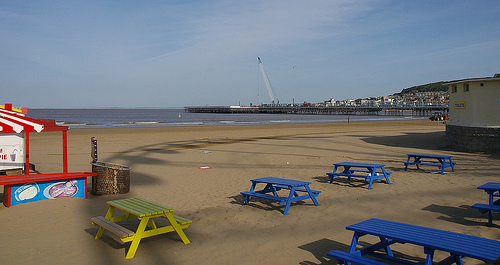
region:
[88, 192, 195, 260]
Yellow picnic table and benches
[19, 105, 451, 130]
The water appears calm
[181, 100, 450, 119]
The pier is long above the water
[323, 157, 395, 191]
Blue picnic table and benches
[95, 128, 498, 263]
Shadows on the sand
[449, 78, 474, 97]
Two windows side by side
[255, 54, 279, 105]
White smoke behind a small jet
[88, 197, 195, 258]
yellow picnic bench at beach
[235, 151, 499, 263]
blue picnic benches on beach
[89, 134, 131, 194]
large rock trash bin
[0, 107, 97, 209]
red wooden food stand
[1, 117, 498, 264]
golden sand on beach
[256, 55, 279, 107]
man is flying water rockets on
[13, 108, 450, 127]
water is dark blue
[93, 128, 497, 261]
shadow cast on sand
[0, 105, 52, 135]
red and white awning on food stand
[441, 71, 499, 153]
creme and brick building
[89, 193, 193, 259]
Yellow picnic bench on the sand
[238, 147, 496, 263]
Blue picnic benches on the sand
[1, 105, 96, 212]
Empty food stand on the beach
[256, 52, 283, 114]
Crane in the distance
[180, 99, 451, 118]
Pier jetting out into the water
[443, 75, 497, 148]
Building at the beach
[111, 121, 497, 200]
Shadows in the sand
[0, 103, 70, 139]
Red and white awning on food structure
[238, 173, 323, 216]
Blue picnic bench on the sand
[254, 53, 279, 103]
crane towers over the pier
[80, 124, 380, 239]
shadow of a ferris wheel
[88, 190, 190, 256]
a lone yellow picnic table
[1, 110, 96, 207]
red concession stand with white stripes on roof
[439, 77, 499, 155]
building on the beach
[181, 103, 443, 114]
long pier stretches into the water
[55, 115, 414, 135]
waves lapping at the shore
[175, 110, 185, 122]
bouy in the water just off the beach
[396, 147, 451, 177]
blue table near a lake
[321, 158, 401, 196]
table near a lake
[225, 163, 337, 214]
table near a lake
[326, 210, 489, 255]
table near a lake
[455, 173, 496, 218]
table near a lake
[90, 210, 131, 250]
bench seat near a table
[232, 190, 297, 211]
bench near a table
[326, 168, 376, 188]
bench seat near a table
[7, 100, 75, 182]
house near a lake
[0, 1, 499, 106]
cloud cover in sky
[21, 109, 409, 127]
surface of calm water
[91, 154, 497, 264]
yellow and blue picnic tables